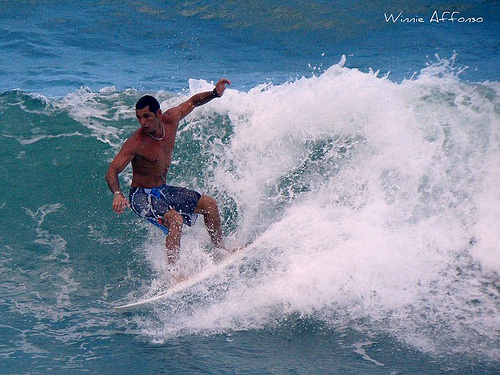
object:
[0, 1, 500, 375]
water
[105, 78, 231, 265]
surfer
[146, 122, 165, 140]
necklace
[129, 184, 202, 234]
shorts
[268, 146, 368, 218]
water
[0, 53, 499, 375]
wave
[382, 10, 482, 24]
print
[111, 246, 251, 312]
surferboard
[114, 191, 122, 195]
watch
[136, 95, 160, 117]
hair